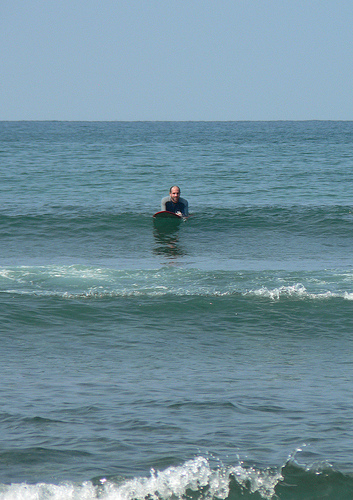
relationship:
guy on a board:
[160, 185, 188, 218] [152, 211, 181, 218]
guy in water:
[160, 185, 188, 218] [1, 122, 353, 500]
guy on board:
[158, 184, 190, 221] [152, 211, 181, 218]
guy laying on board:
[158, 184, 190, 221] [152, 211, 181, 218]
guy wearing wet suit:
[160, 185, 188, 218] [158, 194, 191, 215]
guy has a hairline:
[160, 185, 188, 218] [167, 182, 183, 194]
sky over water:
[1, 1, 352, 122] [1, 122, 353, 500]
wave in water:
[2, 447, 352, 499] [1, 122, 353, 500]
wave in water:
[2, 264, 351, 310] [1, 122, 353, 500]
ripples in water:
[0, 208, 352, 232] [1, 122, 353, 500]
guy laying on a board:
[160, 185, 188, 218] [150, 208, 183, 223]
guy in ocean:
[160, 185, 188, 218] [1, 120, 351, 499]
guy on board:
[160, 185, 188, 218] [152, 211, 181, 218]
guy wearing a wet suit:
[160, 185, 188, 218] [158, 194, 191, 215]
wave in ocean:
[2, 447, 352, 499] [1, 120, 351, 499]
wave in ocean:
[2, 264, 351, 310] [1, 120, 351, 499]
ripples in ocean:
[0, 208, 352, 232] [1, 120, 351, 499]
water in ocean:
[1, 122, 353, 500] [1, 120, 351, 499]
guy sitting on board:
[160, 185, 188, 218] [152, 211, 181, 218]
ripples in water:
[3, 197, 351, 499] [1, 122, 353, 500]